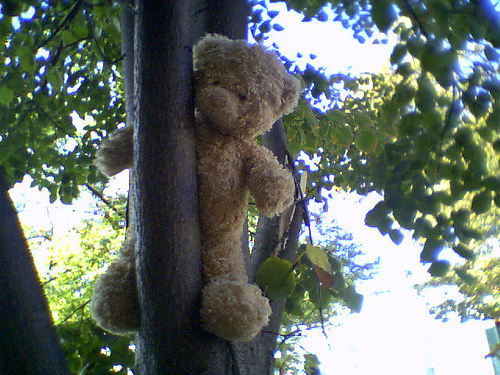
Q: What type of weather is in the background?
A: It is clear.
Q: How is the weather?
A: It is clear.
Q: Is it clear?
A: Yes, it is clear.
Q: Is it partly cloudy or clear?
A: It is clear.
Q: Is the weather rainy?
A: No, it is clear.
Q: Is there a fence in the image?
A: No, there are no fences.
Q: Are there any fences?
A: No, there are no fences.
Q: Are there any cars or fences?
A: No, there are no fences or cars.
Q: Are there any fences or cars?
A: No, there are no fences or cars.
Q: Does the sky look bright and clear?
A: Yes, the sky is bright and clear.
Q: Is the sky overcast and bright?
A: No, the sky is bright but clear.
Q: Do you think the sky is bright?
A: Yes, the sky is bright.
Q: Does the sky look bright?
A: Yes, the sky is bright.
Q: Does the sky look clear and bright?
A: Yes, the sky is clear and bright.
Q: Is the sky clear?
A: Yes, the sky is clear.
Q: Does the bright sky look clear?
A: Yes, the sky is clear.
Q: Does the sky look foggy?
A: No, the sky is clear.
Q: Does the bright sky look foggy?
A: No, the sky is clear.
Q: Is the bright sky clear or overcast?
A: The sky is clear.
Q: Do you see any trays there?
A: No, there are no trays.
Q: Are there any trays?
A: No, there are no trays.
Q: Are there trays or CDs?
A: No, there are no trays or cds.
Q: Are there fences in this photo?
A: No, there are no fences.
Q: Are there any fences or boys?
A: No, there are no fences or boys.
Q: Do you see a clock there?
A: No, there are no clocks.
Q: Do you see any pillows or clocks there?
A: No, there are no clocks or pillows.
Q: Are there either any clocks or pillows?
A: No, there are no clocks or pillows.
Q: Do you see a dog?
A: No, there are no dogs.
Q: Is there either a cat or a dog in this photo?
A: No, there are no dogs or cats.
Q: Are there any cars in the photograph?
A: No, there are no cars.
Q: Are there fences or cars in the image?
A: No, there are no cars or fences.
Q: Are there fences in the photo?
A: No, there are no fences.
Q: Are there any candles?
A: No, there are no candles.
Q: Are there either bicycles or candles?
A: No, there are no candles or bicycles.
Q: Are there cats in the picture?
A: No, there are no cats.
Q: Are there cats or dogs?
A: No, there are no cats or dogs.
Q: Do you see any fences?
A: No, there are no fences.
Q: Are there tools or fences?
A: No, there are no fences or tools.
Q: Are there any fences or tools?
A: No, there are no fences or tools.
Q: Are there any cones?
A: No, there are no cones.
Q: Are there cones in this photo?
A: No, there are no cones.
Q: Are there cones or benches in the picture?
A: No, there are no cones or benches.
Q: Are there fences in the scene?
A: No, there are no fences.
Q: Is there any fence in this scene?
A: No, there are no fences.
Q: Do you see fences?
A: No, there are no fences.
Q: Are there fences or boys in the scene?
A: No, there are no fences or boys.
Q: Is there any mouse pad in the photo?
A: No, there are no mouse pads.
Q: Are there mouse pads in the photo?
A: No, there are no mouse pads.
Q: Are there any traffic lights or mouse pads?
A: No, there are no mouse pads or traffic lights.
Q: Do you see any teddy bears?
A: Yes, there is a teddy bear.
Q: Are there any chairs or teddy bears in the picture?
A: Yes, there is a teddy bear.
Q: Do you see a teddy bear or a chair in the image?
A: Yes, there is a teddy bear.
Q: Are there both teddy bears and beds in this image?
A: No, there is a teddy bear but no beds.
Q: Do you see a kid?
A: No, there are no children.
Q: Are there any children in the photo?
A: No, there are no children.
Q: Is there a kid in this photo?
A: No, there are no children.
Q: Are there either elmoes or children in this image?
A: No, there are no children or elmoes.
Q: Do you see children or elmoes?
A: No, there are no children or elmoes.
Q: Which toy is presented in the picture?
A: The toy is a teddy bear.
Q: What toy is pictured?
A: The toy is a teddy bear.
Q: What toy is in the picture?
A: The toy is a teddy bear.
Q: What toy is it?
A: The toy is a teddy bear.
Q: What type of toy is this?
A: This is a teddy bear.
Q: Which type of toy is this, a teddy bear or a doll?
A: This is a teddy bear.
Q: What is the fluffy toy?
A: The toy is a teddy bear.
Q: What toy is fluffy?
A: The toy is a teddy bear.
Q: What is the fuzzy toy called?
A: The toy is a teddy bear.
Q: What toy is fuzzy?
A: The toy is a teddy bear.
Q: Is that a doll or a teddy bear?
A: That is a teddy bear.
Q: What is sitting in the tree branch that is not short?
A: The teddy bear is sitting in the tree branch.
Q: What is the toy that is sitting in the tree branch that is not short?
A: The toy is a teddy bear.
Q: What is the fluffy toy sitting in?
A: The teddy bear is sitting in the tree branch.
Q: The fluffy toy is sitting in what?
A: The teddy bear is sitting in the tree branch.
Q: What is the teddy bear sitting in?
A: The teddy bear is sitting in the tree branch.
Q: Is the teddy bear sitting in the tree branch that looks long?
A: Yes, the teddy bear is sitting in the tree branch.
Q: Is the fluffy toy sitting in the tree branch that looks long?
A: Yes, the teddy bear is sitting in the tree branch.